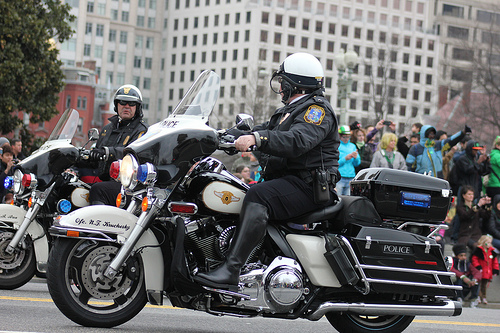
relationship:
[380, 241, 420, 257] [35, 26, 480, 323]
lettering on motorcycle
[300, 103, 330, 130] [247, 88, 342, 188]
logo on jacket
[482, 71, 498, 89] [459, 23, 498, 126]
limbs on tree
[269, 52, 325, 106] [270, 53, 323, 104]
helmet on head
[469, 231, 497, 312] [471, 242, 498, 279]
child on coat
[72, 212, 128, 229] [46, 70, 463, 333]
name on bike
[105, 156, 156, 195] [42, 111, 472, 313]
lights on motorcycle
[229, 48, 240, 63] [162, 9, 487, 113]
windows on building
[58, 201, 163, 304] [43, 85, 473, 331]
fender on bike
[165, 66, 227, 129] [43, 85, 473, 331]
windshield on bike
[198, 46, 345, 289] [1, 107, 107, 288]
man on motorcycle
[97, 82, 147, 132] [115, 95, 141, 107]
man on sunglasses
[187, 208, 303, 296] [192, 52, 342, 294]
boot on man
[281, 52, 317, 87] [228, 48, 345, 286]
helmet on officer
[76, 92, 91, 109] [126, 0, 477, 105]
windows on building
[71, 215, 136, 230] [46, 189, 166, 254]
script on fender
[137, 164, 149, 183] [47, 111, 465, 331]
light on motorcycle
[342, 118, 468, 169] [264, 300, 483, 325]
crowd near street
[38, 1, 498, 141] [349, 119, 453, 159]
building behind crowd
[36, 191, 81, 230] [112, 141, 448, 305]
blue light on motorcycle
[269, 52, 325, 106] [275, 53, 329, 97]
helmet on head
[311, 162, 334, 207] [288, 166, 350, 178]
walkietalkie on belt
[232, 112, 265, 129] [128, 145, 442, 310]
mirror on motorcycle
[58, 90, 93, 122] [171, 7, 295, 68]
wall of building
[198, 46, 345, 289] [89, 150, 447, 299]
man riding motorcycle